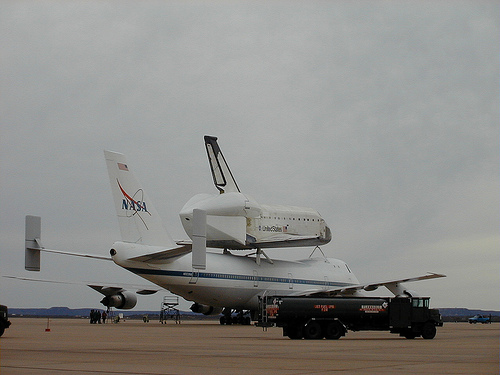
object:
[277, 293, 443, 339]
truck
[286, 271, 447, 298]
wing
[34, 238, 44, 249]
pole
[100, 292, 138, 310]
turbine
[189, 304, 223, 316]
turbine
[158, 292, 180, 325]
staircase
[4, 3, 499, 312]
sky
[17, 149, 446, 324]
airplane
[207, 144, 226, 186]
rectangle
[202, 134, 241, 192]
tail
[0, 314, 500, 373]
concrete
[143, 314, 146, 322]
people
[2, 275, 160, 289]
wing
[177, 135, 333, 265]
plane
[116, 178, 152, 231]
logo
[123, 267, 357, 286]
dark stripe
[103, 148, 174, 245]
tail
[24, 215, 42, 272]
rectangle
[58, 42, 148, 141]
section